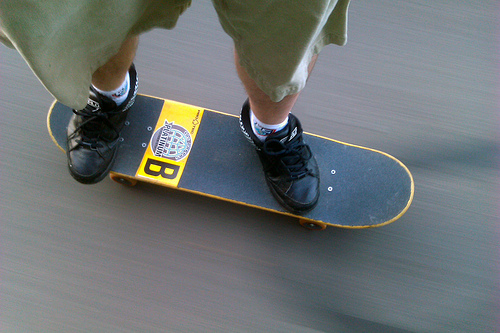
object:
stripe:
[133, 98, 205, 188]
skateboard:
[36, 86, 423, 238]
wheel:
[105, 170, 140, 190]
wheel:
[295, 215, 330, 233]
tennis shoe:
[237, 93, 329, 215]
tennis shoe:
[59, 60, 140, 187]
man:
[0, 0, 353, 215]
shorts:
[0, 1, 354, 114]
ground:
[0, 1, 498, 327]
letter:
[143, 156, 181, 181]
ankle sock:
[247, 110, 292, 143]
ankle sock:
[91, 72, 136, 105]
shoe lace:
[261, 117, 314, 184]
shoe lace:
[63, 103, 119, 154]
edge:
[106, 171, 357, 231]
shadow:
[387, 128, 499, 181]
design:
[252, 121, 276, 138]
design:
[112, 81, 131, 100]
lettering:
[286, 126, 300, 146]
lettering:
[86, 97, 100, 110]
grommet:
[329, 168, 338, 176]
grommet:
[326, 185, 334, 193]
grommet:
[146, 126, 154, 131]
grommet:
[141, 142, 148, 148]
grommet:
[124, 120, 130, 126]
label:
[148, 118, 194, 163]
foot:
[237, 96, 324, 216]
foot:
[60, 62, 139, 186]